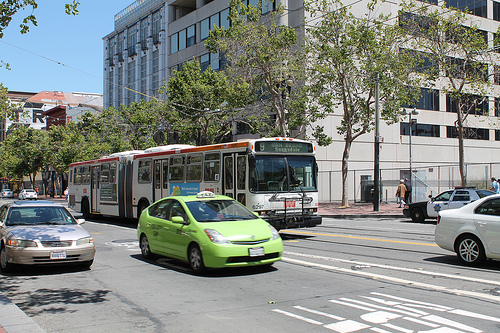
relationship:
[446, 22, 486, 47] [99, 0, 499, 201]
window on building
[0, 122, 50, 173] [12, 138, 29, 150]
plant has leaf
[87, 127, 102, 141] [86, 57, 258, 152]
leaf on a plant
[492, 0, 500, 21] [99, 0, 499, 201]
window decorates building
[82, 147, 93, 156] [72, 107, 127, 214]
leaf on plant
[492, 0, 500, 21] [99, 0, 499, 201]
window on building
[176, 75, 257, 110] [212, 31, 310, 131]
leaf on plant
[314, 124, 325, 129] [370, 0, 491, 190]
leaf on plant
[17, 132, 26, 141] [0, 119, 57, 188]
leaf on plant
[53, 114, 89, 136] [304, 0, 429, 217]
leaf on plant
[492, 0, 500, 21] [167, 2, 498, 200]
window on building